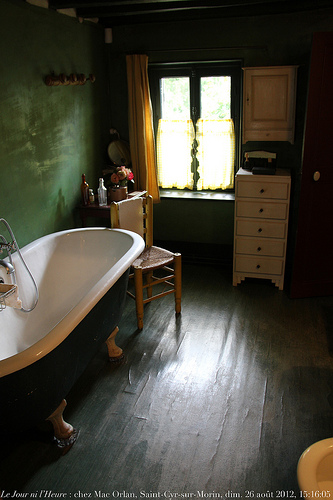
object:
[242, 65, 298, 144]
cabinet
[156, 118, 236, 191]
curtains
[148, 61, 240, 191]
window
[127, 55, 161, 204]
curtain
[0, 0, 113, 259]
wall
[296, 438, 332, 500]
toilet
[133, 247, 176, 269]
seat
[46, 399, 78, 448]
claw feet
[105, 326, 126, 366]
claw feet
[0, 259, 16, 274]
spout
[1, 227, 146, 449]
bathtub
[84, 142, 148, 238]
shelf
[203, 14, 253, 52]
wall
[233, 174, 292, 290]
cabinet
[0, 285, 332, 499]
floor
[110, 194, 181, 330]
chair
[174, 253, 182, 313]
leg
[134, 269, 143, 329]
leg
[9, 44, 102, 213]
exterior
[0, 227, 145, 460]
porcelain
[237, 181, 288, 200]
drawer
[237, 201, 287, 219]
drawer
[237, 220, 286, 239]
drawer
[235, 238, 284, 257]
drawer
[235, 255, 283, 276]
drawer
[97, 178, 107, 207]
bottle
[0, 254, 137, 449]
exterior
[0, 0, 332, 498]
bathroom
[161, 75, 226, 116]
light